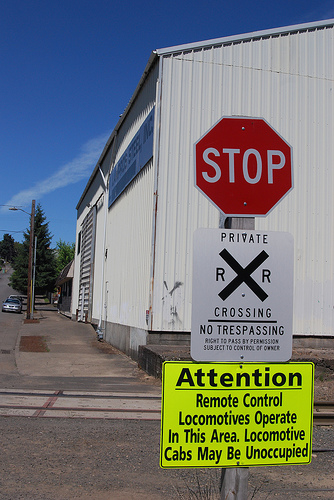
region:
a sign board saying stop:
[212, 123, 301, 192]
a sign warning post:
[158, 359, 314, 451]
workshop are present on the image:
[98, 170, 197, 332]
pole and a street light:
[9, 193, 42, 252]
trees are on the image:
[35, 209, 59, 298]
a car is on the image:
[0, 298, 20, 315]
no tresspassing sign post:
[204, 305, 281, 340]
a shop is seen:
[57, 274, 71, 303]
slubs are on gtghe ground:
[14, 383, 154, 423]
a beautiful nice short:
[18, 312, 245, 498]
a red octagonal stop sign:
[197, 118, 294, 217]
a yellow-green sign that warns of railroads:
[163, 360, 311, 463]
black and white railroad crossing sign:
[194, 229, 293, 362]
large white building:
[70, 132, 328, 332]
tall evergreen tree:
[17, 209, 55, 294]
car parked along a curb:
[0, 298, 24, 315]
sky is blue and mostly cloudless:
[2, 1, 111, 133]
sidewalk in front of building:
[20, 306, 65, 373]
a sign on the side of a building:
[101, 108, 158, 209]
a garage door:
[76, 209, 93, 324]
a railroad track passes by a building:
[10, 390, 155, 421]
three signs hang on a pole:
[161, 108, 317, 494]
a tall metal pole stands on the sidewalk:
[33, 235, 34, 317]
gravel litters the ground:
[11, 424, 149, 477]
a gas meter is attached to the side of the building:
[97, 325, 105, 340]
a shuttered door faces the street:
[77, 211, 93, 323]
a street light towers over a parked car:
[9, 206, 33, 320]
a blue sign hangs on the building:
[105, 109, 152, 207]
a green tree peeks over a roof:
[59, 242, 72, 260]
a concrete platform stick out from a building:
[140, 346, 186, 362]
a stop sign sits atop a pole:
[189, 102, 318, 219]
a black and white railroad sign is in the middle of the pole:
[181, 222, 299, 366]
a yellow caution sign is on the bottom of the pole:
[149, 353, 305, 482]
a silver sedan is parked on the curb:
[3, 297, 24, 314]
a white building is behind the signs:
[76, 177, 179, 322]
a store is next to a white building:
[56, 262, 80, 315]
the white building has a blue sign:
[106, 123, 148, 201]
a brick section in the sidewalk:
[18, 335, 51, 354]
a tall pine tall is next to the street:
[33, 210, 53, 289]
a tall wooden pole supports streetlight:
[27, 200, 36, 322]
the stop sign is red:
[191, 109, 297, 218]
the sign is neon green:
[157, 355, 316, 469]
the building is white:
[72, 14, 332, 338]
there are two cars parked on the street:
[1, 291, 24, 314]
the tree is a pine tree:
[6, 198, 64, 295]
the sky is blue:
[2, 2, 331, 242]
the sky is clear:
[0, 3, 333, 247]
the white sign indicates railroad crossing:
[188, 225, 299, 364]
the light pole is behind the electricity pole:
[8, 205, 38, 320]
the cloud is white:
[2, 128, 115, 213]